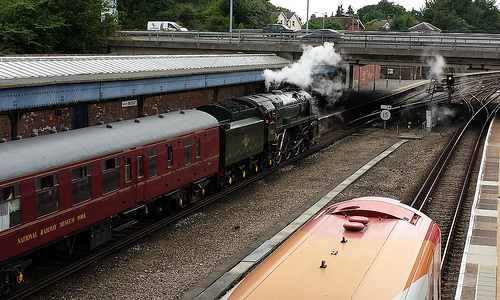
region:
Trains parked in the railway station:
[132, 120, 437, 270]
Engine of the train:
[268, 94, 325, 141]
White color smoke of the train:
[261, 47, 348, 82]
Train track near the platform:
[440, 123, 467, 183]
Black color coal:
[224, 98, 254, 148]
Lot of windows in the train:
[2, 137, 223, 187]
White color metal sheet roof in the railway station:
[20, 52, 215, 70]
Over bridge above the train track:
[206, 31, 458, 48]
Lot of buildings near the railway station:
[273, 4, 448, 24]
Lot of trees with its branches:
[12, 2, 100, 42]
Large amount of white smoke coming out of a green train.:
[263, 42, 343, 92]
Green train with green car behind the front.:
[198, 88, 321, 180]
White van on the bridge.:
[145, 18, 188, 31]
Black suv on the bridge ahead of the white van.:
[260, 20, 294, 35]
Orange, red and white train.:
[228, 197, 443, 299]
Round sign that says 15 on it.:
[378, 108, 390, 121]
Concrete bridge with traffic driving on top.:
[113, 25, 498, 62]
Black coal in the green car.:
[213, 95, 249, 114]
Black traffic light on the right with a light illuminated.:
[446, 72, 455, 89]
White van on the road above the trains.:
[148, 19, 188, 33]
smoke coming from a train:
[251, 43, 336, 115]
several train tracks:
[385, 69, 492, 119]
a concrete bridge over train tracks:
[160, 24, 485, 64]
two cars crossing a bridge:
[204, 12, 400, 49]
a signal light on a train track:
[441, 64, 466, 109]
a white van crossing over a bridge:
[127, 18, 193, 42]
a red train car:
[1, 112, 224, 272]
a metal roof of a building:
[0, 52, 262, 84]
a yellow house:
[266, 6, 303, 28]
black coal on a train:
[211, 89, 261, 123]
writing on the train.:
[26, 210, 85, 245]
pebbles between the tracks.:
[172, 238, 204, 264]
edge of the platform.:
[470, 222, 495, 287]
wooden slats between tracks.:
[442, 169, 457, 208]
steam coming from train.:
[294, 49, 324, 80]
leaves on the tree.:
[35, 13, 53, 26]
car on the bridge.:
[301, 26, 337, 38]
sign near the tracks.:
[375, 105, 392, 130]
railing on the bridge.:
[437, 34, 479, 49]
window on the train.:
[102, 160, 119, 190]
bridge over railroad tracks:
[356, 12, 494, 123]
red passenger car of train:
[3, 98, 222, 271]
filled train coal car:
[206, 88, 267, 189]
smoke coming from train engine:
[258, 53, 331, 127]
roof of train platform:
[3, 46, 208, 123]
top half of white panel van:
[142, 16, 190, 31]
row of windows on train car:
[8, 146, 205, 220]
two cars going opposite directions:
[254, 13, 343, 49]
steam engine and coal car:
[204, 70, 329, 177]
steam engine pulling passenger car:
[11, 71, 321, 224]